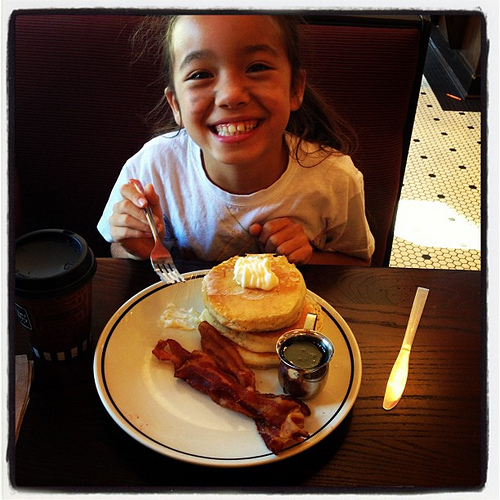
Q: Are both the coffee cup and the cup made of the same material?
A: Yes, both the coffee cup and the cup are made of plastic.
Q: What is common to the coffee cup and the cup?
A: The material, both the coffee cup and the cup are plastic.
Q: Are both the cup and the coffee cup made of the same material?
A: Yes, both the cup and the coffee cup are made of plastic.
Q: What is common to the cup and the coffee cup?
A: The material, both the cup and the coffee cup are plastic.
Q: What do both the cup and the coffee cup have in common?
A: The material, both the cup and the coffee cup are plastic.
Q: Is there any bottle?
A: No, there are no bottles.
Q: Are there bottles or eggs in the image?
A: No, there are no bottles or eggs.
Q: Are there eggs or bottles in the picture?
A: No, there are no bottles or eggs.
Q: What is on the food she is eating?
A: The butter is on the pancakes.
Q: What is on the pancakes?
A: The butter is on the pancakes.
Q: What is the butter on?
A: The butter is on the pancakes.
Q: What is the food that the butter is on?
A: The food is pancakes.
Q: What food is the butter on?
A: The butter is on the pancakes.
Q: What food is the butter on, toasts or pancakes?
A: The butter is on pancakes.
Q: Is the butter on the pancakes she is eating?
A: Yes, the butter is on the pancakes.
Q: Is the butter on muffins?
A: No, the butter is on the pancakes.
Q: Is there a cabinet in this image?
A: No, there are no cabinets.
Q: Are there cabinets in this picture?
A: No, there are no cabinets.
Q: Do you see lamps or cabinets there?
A: No, there are no cabinets or lamps.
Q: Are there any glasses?
A: No, there are no glasses.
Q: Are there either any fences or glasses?
A: No, there are no glasses or fences.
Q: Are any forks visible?
A: Yes, there is a fork.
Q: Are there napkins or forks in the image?
A: Yes, there is a fork.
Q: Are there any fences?
A: No, there are no fences.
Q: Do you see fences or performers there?
A: No, there are no fences or performers.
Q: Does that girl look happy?
A: Yes, the girl is happy.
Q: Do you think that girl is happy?
A: Yes, the girl is happy.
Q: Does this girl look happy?
A: Yes, the girl is happy.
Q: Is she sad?
A: No, the girl is happy.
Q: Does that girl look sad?
A: No, the girl is happy.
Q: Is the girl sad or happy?
A: The girl is happy.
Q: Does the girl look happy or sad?
A: The girl is happy.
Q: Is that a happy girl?
A: Yes, that is a happy girl.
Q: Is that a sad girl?
A: No, that is a happy girl.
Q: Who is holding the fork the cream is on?
A: The girl is holding the fork.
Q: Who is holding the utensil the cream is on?
A: The girl is holding the fork.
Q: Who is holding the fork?
A: The girl is holding the fork.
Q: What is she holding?
A: The girl is holding the fork.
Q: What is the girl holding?
A: The girl is holding the fork.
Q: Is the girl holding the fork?
A: Yes, the girl is holding the fork.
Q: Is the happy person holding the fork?
A: Yes, the girl is holding the fork.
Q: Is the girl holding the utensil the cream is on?
A: Yes, the girl is holding the fork.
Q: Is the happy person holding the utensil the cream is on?
A: Yes, the girl is holding the fork.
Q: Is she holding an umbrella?
A: No, the girl is holding the fork.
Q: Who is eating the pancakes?
A: The girl is eating the pancakes.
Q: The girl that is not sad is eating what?
A: The girl is eating pancakes.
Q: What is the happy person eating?
A: The girl is eating pancakes.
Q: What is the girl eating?
A: The girl is eating pancakes.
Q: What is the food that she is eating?
A: The food is pancakes.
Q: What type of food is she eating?
A: The girl is eating pancakes.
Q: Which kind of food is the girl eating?
A: The girl is eating pancakes.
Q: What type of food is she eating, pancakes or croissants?
A: The girl is eating pancakes.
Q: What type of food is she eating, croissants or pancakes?
A: The girl is eating pancakes.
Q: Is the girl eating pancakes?
A: Yes, the girl is eating pancakes.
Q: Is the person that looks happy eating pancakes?
A: Yes, the girl is eating pancakes.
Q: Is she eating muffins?
A: No, the girl is eating pancakes.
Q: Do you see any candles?
A: No, there are no candles.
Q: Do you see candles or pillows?
A: No, there are no candles or pillows.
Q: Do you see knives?
A: Yes, there is a knife.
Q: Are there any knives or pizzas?
A: Yes, there is a knife.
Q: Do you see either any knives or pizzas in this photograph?
A: Yes, there is a knife.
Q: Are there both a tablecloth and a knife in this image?
A: No, there is a knife but no tablecloths.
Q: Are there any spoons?
A: No, there are no spoons.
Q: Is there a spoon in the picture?
A: No, there are no spoons.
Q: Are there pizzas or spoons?
A: No, there are no spoons or pizzas.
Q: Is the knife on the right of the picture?
A: Yes, the knife is on the right of the image.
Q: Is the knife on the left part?
A: No, the knife is on the right of the image.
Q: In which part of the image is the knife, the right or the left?
A: The knife is on the right of the image.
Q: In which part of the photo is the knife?
A: The knife is on the right of the image.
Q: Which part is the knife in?
A: The knife is on the right of the image.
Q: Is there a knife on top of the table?
A: Yes, there is a knife on top of the table.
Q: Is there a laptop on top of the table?
A: No, there is a knife on top of the table.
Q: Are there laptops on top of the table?
A: No, there is a knife on top of the table.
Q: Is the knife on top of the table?
A: Yes, the knife is on top of the table.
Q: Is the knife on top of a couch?
A: No, the knife is on top of the table.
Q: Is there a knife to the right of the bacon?
A: Yes, there is a knife to the right of the bacon.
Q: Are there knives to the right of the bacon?
A: Yes, there is a knife to the right of the bacon.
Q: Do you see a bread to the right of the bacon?
A: No, there is a knife to the right of the bacon.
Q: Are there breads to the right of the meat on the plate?
A: No, there is a knife to the right of the bacon.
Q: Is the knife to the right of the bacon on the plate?
A: Yes, the knife is to the right of the bacon.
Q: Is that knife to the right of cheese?
A: No, the knife is to the right of the bacon.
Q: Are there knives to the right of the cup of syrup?
A: Yes, there is a knife to the right of the cup.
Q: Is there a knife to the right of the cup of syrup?
A: Yes, there is a knife to the right of the cup.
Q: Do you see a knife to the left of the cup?
A: No, the knife is to the right of the cup.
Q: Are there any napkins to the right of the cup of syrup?
A: No, there is a knife to the right of the cup.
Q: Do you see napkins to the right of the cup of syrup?
A: No, there is a knife to the right of the cup.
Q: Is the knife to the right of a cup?
A: Yes, the knife is to the right of a cup.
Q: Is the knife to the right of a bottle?
A: No, the knife is to the right of a cup.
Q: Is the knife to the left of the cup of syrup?
A: No, the knife is to the right of the cup.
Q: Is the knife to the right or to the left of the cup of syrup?
A: The knife is to the right of the cup.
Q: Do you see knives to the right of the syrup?
A: Yes, there is a knife to the right of the syrup.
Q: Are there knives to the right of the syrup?
A: Yes, there is a knife to the right of the syrup.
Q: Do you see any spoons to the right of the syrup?
A: No, there is a knife to the right of the syrup.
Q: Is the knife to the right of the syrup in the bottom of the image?
A: Yes, the knife is to the right of the syrup.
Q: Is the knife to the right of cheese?
A: No, the knife is to the right of the syrup.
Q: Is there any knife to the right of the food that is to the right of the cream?
A: Yes, there is a knife to the right of the pancakes.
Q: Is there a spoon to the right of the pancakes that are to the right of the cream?
A: No, there is a knife to the right of the pancakes.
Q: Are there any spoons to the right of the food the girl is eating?
A: No, there is a knife to the right of the pancakes.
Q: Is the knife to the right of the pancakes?
A: Yes, the knife is to the right of the pancakes.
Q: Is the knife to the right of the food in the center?
A: Yes, the knife is to the right of the pancakes.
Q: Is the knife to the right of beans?
A: No, the knife is to the right of the pancakes.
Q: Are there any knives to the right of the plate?
A: Yes, there is a knife to the right of the plate.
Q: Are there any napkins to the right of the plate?
A: No, there is a knife to the right of the plate.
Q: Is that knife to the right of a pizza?
A: No, the knife is to the right of the plate.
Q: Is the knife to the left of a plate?
A: No, the knife is to the right of a plate.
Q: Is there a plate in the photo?
A: Yes, there is a plate.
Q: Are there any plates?
A: Yes, there is a plate.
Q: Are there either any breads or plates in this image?
A: Yes, there is a plate.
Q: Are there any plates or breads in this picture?
A: Yes, there is a plate.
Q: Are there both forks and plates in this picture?
A: Yes, there are both a plate and a fork.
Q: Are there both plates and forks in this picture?
A: Yes, there are both a plate and a fork.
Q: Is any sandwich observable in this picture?
A: No, there are no sandwiches.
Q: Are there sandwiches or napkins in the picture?
A: No, there are no sandwiches or napkins.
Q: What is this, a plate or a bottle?
A: This is a plate.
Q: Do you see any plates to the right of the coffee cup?
A: Yes, there is a plate to the right of the coffee cup.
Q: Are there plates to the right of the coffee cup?
A: Yes, there is a plate to the right of the coffee cup.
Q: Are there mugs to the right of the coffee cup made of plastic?
A: No, there is a plate to the right of the coffee cup.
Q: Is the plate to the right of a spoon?
A: No, the plate is to the right of a coffee cup.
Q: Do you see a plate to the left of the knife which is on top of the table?
A: Yes, there is a plate to the left of the knife.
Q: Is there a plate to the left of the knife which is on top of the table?
A: Yes, there is a plate to the left of the knife.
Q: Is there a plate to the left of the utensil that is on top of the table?
A: Yes, there is a plate to the left of the knife.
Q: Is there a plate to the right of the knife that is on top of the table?
A: No, the plate is to the left of the knife.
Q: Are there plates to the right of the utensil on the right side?
A: No, the plate is to the left of the knife.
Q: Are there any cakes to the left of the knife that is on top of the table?
A: No, there is a plate to the left of the knife.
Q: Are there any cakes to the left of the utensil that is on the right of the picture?
A: No, there is a plate to the left of the knife.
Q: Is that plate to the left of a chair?
A: No, the plate is to the left of the knife.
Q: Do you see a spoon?
A: No, there are no spoons.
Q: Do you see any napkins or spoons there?
A: No, there are no spoons or napkins.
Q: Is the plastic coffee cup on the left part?
A: Yes, the coffee cup is on the left of the image.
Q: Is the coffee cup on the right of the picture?
A: No, the coffee cup is on the left of the image.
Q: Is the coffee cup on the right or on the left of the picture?
A: The coffee cup is on the left of the image.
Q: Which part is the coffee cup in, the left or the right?
A: The coffee cup is on the left of the image.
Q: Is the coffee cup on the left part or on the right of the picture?
A: The coffee cup is on the left of the image.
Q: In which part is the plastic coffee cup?
A: The coffee cup is on the left of the image.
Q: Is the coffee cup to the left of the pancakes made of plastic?
A: Yes, the coffee cup is made of plastic.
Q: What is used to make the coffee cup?
A: The coffee cup is made of plastic.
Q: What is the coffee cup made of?
A: The coffee cup is made of plastic.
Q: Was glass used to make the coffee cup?
A: No, the coffee cup is made of plastic.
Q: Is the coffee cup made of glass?
A: No, the coffee cup is made of plastic.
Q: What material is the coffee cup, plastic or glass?
A: The coffee cup is made of plastic.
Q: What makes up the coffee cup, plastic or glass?
A: The coffee cup is made of plastic.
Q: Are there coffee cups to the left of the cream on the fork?
A: Yes, there is a coffee cup to the left of the cream.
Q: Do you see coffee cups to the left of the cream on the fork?
A: Yes, there is a coffee cup to the left of the cream.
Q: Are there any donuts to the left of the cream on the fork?
A: No, there is a coffee cup to the left of the cream.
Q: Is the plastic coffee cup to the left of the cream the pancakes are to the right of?
A: Yes, the coffee cup is to the left of the cream.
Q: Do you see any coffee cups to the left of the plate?
A: Yes, there is a coffee cup to the left of the plate.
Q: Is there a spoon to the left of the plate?
A: No, there is a coffee cup to the left of the plate.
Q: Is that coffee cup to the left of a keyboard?
A: No, the coffee cup is to the left of the plate.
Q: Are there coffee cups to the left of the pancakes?
A: Yes, there is a coffee cup to the left of the pancakes.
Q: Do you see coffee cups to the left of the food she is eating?
A: Yes, there is a coffee cup to the left of the pancakes.